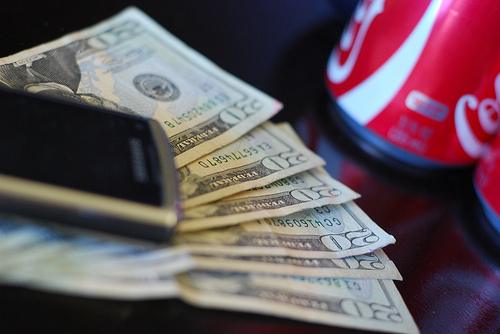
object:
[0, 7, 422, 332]
money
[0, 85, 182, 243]
cell phone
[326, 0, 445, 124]
white stripe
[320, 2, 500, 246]
soda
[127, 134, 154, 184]
phone logo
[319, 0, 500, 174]
coke can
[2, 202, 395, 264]
bill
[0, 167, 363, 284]
bill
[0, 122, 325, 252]
bill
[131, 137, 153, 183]
cellphone brand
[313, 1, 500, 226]
coca cola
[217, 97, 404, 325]
20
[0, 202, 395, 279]
bill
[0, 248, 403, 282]
bill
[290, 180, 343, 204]
"twenty"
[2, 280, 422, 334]
bill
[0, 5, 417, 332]
stack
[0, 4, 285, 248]
bill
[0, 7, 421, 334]
twenty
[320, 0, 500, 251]
can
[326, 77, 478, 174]
bottom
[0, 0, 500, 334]
table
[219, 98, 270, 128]
number twenty